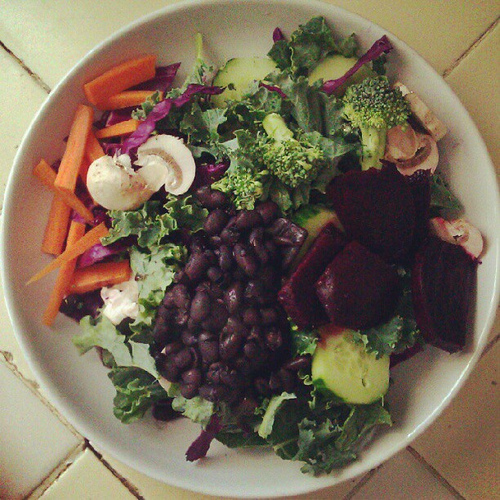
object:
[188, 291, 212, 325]
beans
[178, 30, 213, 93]
lettuce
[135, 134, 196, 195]
mushrooms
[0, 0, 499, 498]
plate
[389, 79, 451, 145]
vegetables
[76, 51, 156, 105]
carrots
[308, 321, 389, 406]
cucumber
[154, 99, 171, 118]
beet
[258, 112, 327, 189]
broccoli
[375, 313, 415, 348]
cabbage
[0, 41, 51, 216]
tile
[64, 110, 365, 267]
salad